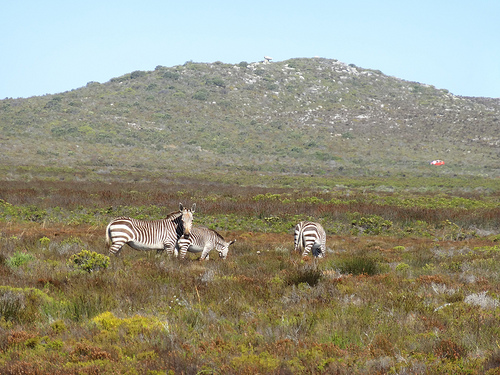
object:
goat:
[262, 56, 273, 64]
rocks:
[83, 52, 500, 147]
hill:
[0, 55, 500, 171]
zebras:
[267, 221, 327, 266]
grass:
[0, 269, 500, 374]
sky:
[0, 0, 500, 98]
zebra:
[170, 226, 237, 267]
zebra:
[294, 220, 327, 264]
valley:
[0, 156, 499, 375]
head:
[178, 202, 197, 238]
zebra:
[105, 202, 198, 269]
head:
[217, 238, 238, 262]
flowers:
[167, 293, 184, 311]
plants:
[0, 178, 499, 234]